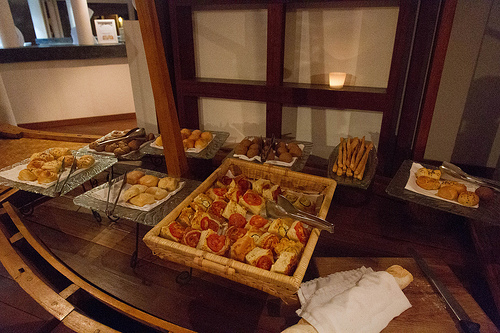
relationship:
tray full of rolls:
[147, 153, 341, 303] [168, 164, 313, 269]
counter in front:
[5, 29, 132, 59] [13, 4, 146, 42]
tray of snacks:
[330, 132, 384, 190] [334, 139, 373, 180]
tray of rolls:
[2, 145, 119, 201] [18, 145, 96, 186]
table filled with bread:
[4, 129, 500, 332] [23, 126, 491, 279]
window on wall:
[184, 4, 399, 166] [136, 2, 471, 158]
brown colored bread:
[236, 137, 302, 162] [238, 138, 306, 167]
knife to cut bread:
[411, 242, 481, 332] [23, 126, 491, 279]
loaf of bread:
[293, 261, 414, 330] [290, 255, 411, 332]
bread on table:
[23, 126, 491, 279] [4, 129, 500, 332]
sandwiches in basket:
[163, 162, 311, 281] [147, 153, 341, 303]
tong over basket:
[266, 188, 336, 237] [147, 153, 341, 303]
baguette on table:
[124, 168, 180, 210] [4, 129, 500, 332]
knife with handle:
[411, 242, 481, 332] [459, 316, 479, 332]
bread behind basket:
[334, 132, 378, 183] [147, 153, 341, 303]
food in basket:
[168, 164, 313, 269] [147, 153, 341, 303]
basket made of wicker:
[147, 153, 341, 303] [148, 157, 338, 295]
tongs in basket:
[266, 188, 336, 237] [147, 153, 341, 303]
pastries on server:
[23, 126, 491, 279] [4, 129, 500, 332]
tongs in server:
[266, 188, 336, 237] [147, 153, 341, 303]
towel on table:
[299, 255, 413, 331] [4, 129, 500, 332]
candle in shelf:
[328, 69, 345, 91] [289, 79, 389, 113]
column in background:
[3, 2, 99, 45] [4, 4, 139, 118]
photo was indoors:
[6, 8, 492, 329] [5, 5, 491, 324]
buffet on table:
[23, 126, 491, 279] [4, 129, 500, 332]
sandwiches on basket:
[163, 162, 311, 281] [147, 153, 341, 303]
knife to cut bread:
[411, 242, 481, 332] [290, 255, 411, 332]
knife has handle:
[411, 242, 481, 332] [459, 316, 479, 332]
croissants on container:
[18, 145, 96, 186] [0, 142, 118, 225]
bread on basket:
[334, 132, 378, 183] [324, 140, 376, 204]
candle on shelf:
[328, 69, 345, 91] [289, 79, 389, 113]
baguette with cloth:
[293, 261, 414, 330] [299, 255, 413, 331]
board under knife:
[314, 254, 497, 332] [411, 242, 481, 332]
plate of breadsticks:
[330, 132, 384, 190] [334, 139, 373, 180]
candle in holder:
[328, 69, 345, 91] [330, 70, 348, 90]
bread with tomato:
[23, 126, 491, 279] [170, 177, 306, 270]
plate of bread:
[227, 133, 311, 173] [238, 138, 306, 167]